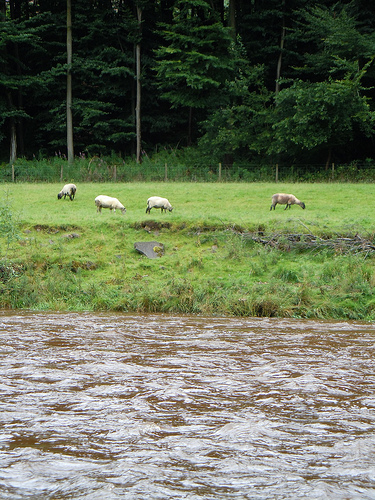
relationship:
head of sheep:
[171, 204, 174, 212] [43, 164, 276, 213]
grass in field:
[200, 190, 235, 213] [171, 254, 289, 285]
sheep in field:
[43, 164, 276, 213] [171, 254, 289, 285]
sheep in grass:
[43, 164, 276, 213] [200, 190, 235, 213]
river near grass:
[73, 332, 120, 350] [200, 190, 235, 213]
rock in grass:
[128, 247, 158, 260] [200, 190, 235, 213]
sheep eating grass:
[43, 164, 276, 213] [200, 190, 235, 213]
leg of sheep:
[140, 206, 158, 215] [43, 164, 276, 213]